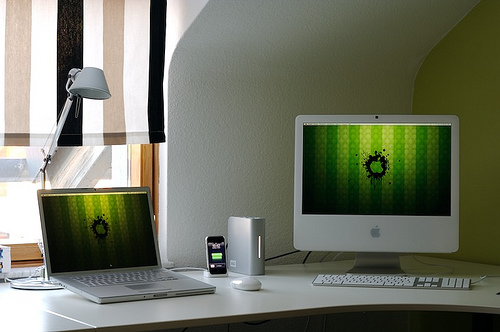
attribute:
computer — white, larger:
[294, 113, 472, 290]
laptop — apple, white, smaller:
[36, 185, 218, 305]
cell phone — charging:
[203, 234, 230, 279]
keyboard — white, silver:
[310, 273, 475, 291]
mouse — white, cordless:
[231, 274, 264, 293]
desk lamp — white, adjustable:
[8, 65, 112, 292]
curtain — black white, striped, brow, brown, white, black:
[1, 0, 167, 144]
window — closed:
[1, 1, 164, 262]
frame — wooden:
[1, 143, 161, 267]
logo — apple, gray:
[368, 224, 383, 238]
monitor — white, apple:
[291, 112, 462, 255]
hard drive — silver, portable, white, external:
[225, 214, 267, 276]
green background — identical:
[305, 128, 451, 210]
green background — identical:
[52, 193, 149, 271]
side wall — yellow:
[407, 1, 500, 266]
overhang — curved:
[167, 0, 479, 87]